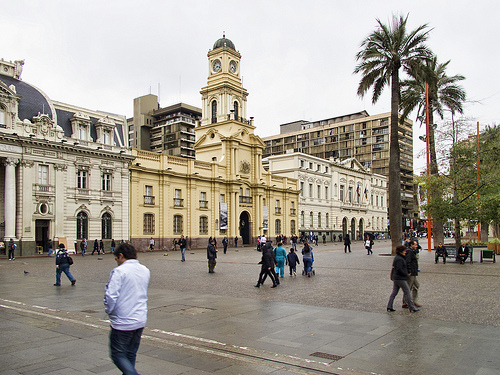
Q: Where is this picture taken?
A: City square.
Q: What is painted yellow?
A: Stone building.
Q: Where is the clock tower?
A: On the tan building.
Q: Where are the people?
A: In the public square.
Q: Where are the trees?
A: In the public square.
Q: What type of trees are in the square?
A: Palm trees.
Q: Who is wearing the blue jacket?
A: The man.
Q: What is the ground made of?
A: Concrete.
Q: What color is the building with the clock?
A: Yellow.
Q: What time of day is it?
A: Afternoon.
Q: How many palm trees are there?
A: Two.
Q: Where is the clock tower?
A: On the yellow building.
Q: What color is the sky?
A: Grey.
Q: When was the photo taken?
A: Daytime.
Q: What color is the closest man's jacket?
A: White.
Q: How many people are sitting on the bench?
A: Two.